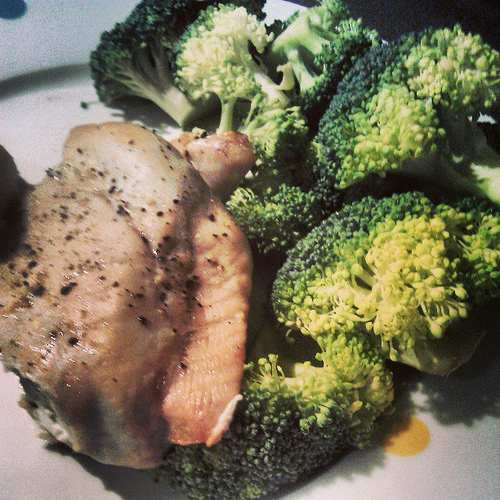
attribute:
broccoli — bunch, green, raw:
[117, 10, 496, 481]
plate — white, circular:
[9, 0, 497, 495]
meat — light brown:
[3, 123, 283, 455]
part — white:
[180, 19, 291, 138]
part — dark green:
[235, 26, 499, 415]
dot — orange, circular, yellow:
[378, 406, 440, 461]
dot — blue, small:
[3, 3, 31, 21]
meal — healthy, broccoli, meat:
[3, 1, 498, 487]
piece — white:
[175, 8, 276, 98]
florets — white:
[181, 2, 373, 155]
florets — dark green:
[166, 23, 500, 487]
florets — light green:
[161, 198, 499, 499]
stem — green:
[135, 41, 209, 119]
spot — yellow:
[370, 409, 436, 460]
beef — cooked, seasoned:
[3, 112, 268, 444]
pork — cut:
[6, 114, 266, 435]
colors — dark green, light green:
[86, 5, 500, 495]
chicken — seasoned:
[4, 117, 268, 450]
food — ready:
[7, 1, 493, 478]